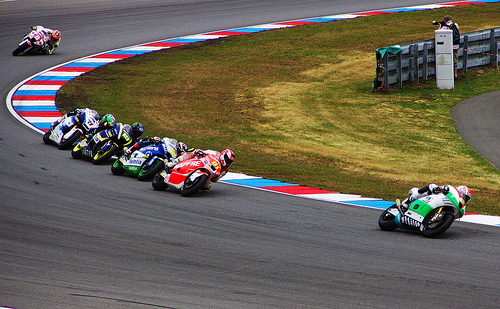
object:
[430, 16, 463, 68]
man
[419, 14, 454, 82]
picture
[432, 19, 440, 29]
camera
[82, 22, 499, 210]
oval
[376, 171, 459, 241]
green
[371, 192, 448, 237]
tires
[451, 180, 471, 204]
man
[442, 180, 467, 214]
green bike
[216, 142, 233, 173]
man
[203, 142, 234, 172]
bike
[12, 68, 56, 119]
striped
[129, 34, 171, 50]
white and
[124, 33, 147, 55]
lines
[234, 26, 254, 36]
blue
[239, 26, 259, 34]
road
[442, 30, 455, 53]
man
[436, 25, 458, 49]
pink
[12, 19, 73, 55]
man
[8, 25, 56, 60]
back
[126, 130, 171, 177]
third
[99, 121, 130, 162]
fourth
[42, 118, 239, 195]
racing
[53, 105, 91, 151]
fifth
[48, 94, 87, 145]
racing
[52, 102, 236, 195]
four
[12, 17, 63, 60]
motorcycle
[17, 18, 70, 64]
behind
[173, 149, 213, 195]
motorbike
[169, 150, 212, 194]
track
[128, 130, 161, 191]
middle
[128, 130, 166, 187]
racing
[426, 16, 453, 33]
man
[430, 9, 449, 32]
video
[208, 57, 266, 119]
grass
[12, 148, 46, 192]
spots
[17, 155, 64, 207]
road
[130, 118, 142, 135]
man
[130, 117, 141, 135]
helmet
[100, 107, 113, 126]
man in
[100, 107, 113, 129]
helmet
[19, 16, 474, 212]
seven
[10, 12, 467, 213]
racing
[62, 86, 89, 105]
grass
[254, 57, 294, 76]
middle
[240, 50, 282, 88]
grass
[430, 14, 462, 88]
man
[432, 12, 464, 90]
camera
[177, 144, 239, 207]
red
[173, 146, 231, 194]
driving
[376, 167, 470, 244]
motorbike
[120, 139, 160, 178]
lime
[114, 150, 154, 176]
bike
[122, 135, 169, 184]
runner up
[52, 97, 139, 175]
racing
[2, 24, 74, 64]
bike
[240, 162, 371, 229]
space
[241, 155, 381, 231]
first bike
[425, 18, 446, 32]
camera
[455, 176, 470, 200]
head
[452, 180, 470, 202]
helmet